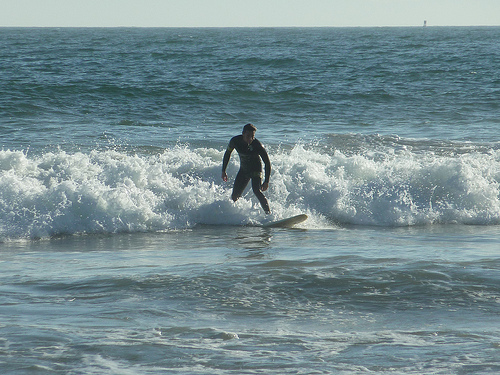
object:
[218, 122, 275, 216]
man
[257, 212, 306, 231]
surfboard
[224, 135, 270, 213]
wetsuit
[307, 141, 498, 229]
wave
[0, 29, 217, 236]
water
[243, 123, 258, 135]
hair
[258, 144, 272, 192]
arm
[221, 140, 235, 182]
arm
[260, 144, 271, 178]
sleeve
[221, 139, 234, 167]
sleeve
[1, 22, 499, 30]
horizon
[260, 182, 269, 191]
hand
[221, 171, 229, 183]
hand